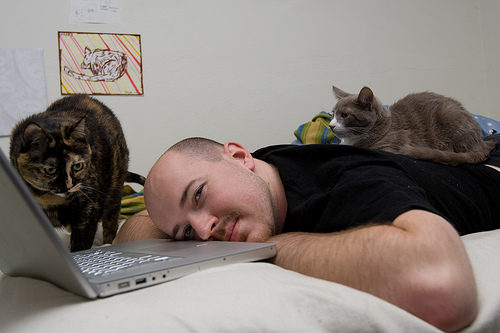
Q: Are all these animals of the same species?
A: Yes, all the animals are cats.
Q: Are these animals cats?
A: Yes, all the animals are cats.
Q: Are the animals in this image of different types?
A: No, all the animals are cats.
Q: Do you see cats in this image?
A: Yes, there is a cat.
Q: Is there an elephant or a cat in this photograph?
A: Yes, there is a cat.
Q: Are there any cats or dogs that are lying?
A: Yes, the cat is lying.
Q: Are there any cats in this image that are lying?
A: Yes, there is a cat that is lying.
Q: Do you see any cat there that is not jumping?
A: Yes, there is a cat that is lying .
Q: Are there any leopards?
A: No, there are no leopards.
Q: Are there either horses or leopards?
A: No, there are no leopards or horses.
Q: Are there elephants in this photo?
A: No, there are no elephants.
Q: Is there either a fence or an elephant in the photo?
A: No, there are no elephants or fences.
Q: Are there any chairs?
A: No, there are no chairs.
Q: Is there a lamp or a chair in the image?
A: No, there are no chairs or lamps.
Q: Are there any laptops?
A: Yes, there is a laptop.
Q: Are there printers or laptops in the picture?
A: Yes, there is a laptop.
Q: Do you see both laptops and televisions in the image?
A: No, there is a laptop but no televisions.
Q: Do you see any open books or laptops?
A: Yes, there is an open laptop.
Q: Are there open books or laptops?
A: Yes, there is an open laptop.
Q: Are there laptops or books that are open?
A: Yes, the laptop is open.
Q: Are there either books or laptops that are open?
A: Yes, the laptop is open.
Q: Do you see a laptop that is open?
A: Yes, there is an open laptop.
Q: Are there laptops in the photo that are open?
A: Yes, there is a laptop that is open.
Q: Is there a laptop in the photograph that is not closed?
A: Yes, there is a open laptop.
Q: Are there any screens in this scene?
A: No, there are no screens.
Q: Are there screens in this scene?
A: No, there are no screens.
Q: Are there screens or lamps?
A: No, there are no screens or lamps.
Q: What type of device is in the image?
A: The device is a laptop.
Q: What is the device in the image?
A: The device is a laptop.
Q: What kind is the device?
A: The device is a laptop.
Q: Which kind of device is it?
A: The device is a laptop.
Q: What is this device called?
A: This is a laptop.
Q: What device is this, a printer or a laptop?
A: This is a laptop.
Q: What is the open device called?
A: The device is a laptop.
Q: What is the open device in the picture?
A: The device is a laptop.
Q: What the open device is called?
A: The device is a laptop.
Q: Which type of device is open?
A: The device is a laptop.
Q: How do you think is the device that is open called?
A: The device is a laptop.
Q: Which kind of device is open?
A: The device is a laptop.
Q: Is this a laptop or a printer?
A: This is a laptop.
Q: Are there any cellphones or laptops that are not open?
A: No, there is a laptop but it is open.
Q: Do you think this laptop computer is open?
A: Yes, the laptop computer is open.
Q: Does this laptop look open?
A: Yes, the laptop is open.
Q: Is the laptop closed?
A: No, the laptop is open.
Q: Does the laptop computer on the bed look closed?
A: No, the laptop computer is open.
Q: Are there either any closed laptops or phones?
A: No, there is a laptop but it is open.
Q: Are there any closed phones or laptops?
A: No, there is a laptop but it is open.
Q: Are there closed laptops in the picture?
A: No, there is a laptop but it is open.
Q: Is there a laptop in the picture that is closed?
A: No, there is a laptop but it is open.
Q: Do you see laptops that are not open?
A: No, there is a laptop but it is open.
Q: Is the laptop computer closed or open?
A: The laptop computer is open.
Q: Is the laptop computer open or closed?
A: The laptop computer is open.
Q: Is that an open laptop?
A: Yes, that is an open laptop.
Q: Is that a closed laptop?
A: No, that is an open laptop.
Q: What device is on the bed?
A: The device is a laptop.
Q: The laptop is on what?
A: The laptop is on the bed.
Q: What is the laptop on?
A: The laptop is on the bed.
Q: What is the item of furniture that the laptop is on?
A: The piece of furniture is a bed.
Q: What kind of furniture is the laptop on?
A: The laptop is on the bed.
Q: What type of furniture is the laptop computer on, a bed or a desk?
A: The laptop computer is on a bed.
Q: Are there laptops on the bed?
A: Yes, there is a laptop on the bed.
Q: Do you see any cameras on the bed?
A: No, there is a laptop on the bed.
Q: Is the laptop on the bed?
A: Yes, the laptop is on the bed.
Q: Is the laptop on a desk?
A: No, the laptop is on the bed.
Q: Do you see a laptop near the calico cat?
A: Yes, there is a laptop near the cat.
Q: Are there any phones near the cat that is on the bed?
A: No, there is a laptop near the cat.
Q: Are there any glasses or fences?
A: No, there are no glasses or fences.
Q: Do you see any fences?
A: No, there are no fences.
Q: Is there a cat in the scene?
A: Yes, there is a cat.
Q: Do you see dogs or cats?
A: Yes, there is a cat.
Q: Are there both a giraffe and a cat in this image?
A: No, there is a cat but no giraffes.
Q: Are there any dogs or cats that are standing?
A: Yes, the cat is standing.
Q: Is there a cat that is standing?
A: Yes, there is a cat that is standing.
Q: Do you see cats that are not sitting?
A: Yes, there is a cat that is standing .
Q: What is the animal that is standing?
A: The animal is a cat.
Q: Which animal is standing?
A: The animal is a cat.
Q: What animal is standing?
A: The animal is a cat.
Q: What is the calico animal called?
A: The animal is a cat.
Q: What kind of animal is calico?
A: The animal is a cat.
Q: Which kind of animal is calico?
A: The animal is a cat.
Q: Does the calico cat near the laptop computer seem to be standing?
A: Yes, the cat is standing.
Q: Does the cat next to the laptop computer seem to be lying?
A: No, the cat is standing.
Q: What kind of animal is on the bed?
A: The animal is a cat.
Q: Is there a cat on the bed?
A: Yes, there is a cat on the bed.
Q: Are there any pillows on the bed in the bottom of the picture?
A: No, there is a cat on the bed.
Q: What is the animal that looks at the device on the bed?
A: The animal is a cat.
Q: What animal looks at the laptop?
A: The animal is a cat.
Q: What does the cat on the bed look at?
A: The cat looks at the laptop.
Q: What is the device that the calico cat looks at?
A: The device is a laptop.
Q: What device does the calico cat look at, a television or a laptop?
A: The cat looks at a laptop.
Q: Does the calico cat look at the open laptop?
A: Yes, the cat looks at the laptop.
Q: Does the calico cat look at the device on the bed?
A: Yes, the cat looks at the laptop.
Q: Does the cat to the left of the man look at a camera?
A: No, the cat looks at the laptop.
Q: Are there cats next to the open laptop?
A: Yes, there is a cat next to the laptop computer.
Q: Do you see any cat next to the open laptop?
A: Yes, there is a cat next to the laptop computer.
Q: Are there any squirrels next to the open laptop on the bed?
A: No, there is a cat next to the laptop computer.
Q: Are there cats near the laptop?
A: Yes, there is a cat near the laptop.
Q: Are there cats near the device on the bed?
A: Yes, there is a cat near the laptop.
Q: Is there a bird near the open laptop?
A: No, there is a cat near the laptop.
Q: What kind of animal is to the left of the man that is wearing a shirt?
A: The animal is a cat.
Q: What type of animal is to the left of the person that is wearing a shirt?
A: The animal is a cat.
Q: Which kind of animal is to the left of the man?
A: The animal is a cat.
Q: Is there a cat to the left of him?
A: Yes, there is a cat to the left of the man.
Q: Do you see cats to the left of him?
A: Yes, there is a cat to the left of the man.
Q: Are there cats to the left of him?
A: Yes, there is a cat to the left of the man.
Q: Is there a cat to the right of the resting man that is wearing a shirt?
A: No, the cat is to the left of the man.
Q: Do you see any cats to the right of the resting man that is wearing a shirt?
A: No, the cat is to the left of the man.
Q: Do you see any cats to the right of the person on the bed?
A: No, the cat is to the left of the man.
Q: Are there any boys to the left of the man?
A: No, there is a cat to the left of the man.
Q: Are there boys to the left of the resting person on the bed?
A: No, there is a cat to the left of the man.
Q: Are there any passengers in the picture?
A: No, there are no passengers.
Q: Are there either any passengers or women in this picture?
A: No, there are no passengers or women.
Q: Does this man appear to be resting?
A: Yes, the man is resting.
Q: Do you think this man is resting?
A: Yes, the man is resting.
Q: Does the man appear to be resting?
A: Yes, the man is resting.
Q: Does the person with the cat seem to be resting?
A: Yes, the man is resting.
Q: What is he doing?
A: The man is resting.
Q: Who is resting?
A: The man is resting.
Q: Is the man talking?
A: No, the man is resting.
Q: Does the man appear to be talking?
A: No, the man is resting.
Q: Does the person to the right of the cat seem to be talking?
A: No, the man is resting.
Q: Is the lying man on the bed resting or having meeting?
A: The man is resting.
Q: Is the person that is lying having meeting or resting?
A: The man is resting.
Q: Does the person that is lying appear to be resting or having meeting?
A: The man is resting.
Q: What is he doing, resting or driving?
A: The man is resting.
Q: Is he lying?
A: Yes, the man is lying.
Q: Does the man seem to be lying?
A: Yes, the man is lying.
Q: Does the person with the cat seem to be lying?
A: Yes, the man is lying.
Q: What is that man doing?
A: The man is lying.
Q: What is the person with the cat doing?
A: The man is lying.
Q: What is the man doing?
A: The man is lying.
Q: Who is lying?
A: The man is lying.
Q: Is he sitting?
A: No, the man is lying.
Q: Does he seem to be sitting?
A: No, the man is lying.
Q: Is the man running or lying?
A: The man is lying.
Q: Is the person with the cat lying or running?
A: The man is lying.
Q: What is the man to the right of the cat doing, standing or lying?
A: The man is lying.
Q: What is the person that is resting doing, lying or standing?
A: The man is lying.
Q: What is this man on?
A: The man is on the bed.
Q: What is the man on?
A: The man is on the bed.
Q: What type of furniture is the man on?
A: The man is on the bed.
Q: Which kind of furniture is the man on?
A: The man is on the bed.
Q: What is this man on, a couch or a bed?
A: The man is on a bed.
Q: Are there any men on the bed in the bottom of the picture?
A: Yes, there is a man on the bed.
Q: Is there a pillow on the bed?
A: No, there is a man on the bed.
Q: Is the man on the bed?
A: Yes, the man is on the bed.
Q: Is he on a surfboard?
A: No, the man is on the bed.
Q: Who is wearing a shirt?
A: The man is wearing a shirt.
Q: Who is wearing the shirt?
A: The man is wearing a shirt.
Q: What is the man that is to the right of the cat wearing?
A: The man is wearing a shirt.